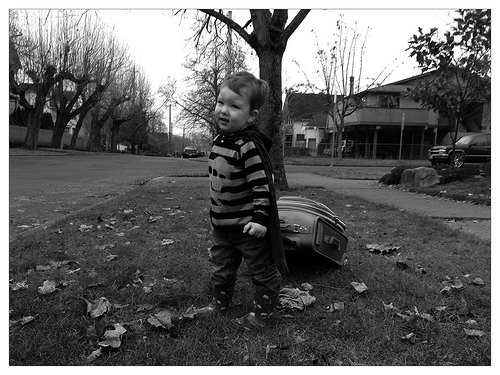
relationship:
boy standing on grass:
[193, 72, 290, 325] [10, 186, 489, 365]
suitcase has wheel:
[275, 197, 349, 270] [343, 258, 350, 270]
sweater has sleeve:
[211, 131, 270, 228] [239, 140, 270, 227]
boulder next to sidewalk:
[401, 167, 439, 192] [284, 172, 493, 239]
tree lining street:
[9, 10, 97, 148] [10, 151, 204, 238]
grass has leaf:
[10, 186, 489, 365] [98, 324, 129, 349]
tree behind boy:
[177, 8, 310, 189] [193, 72, 290, 325]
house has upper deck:
[326, 64, 492, 157] [333, 65, 490, 127]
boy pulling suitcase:
[193, 72, 290, 325] [275, 197, 349, 270]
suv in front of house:
[428, 135, 491, 171] [326, 64, 492, 157]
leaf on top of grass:
[98, 324, 129, 349] [10, 186, 489, 365]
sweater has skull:
[211, 131, 270, 228] [209, 155, 233, 198]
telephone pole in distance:
[165, 102, 178, 157] [83, 75, 200, 172]